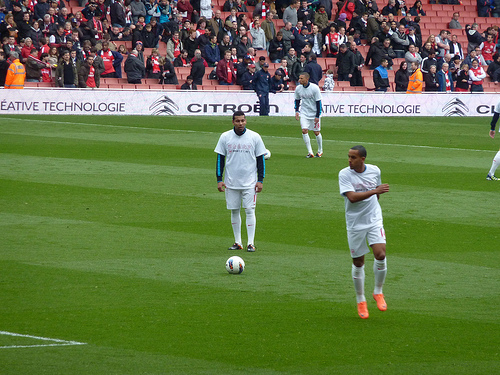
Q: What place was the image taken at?
A: It was taken at the field.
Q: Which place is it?
A: It is a field.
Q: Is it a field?
A: Yes, it is a field.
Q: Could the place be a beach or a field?
A: It is a field.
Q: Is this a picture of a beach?
A: No, the picture is showing a field.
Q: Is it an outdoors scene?
A: Yes, it is outdoors.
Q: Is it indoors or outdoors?
A: It is outdoors.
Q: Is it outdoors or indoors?
A: It is outdoors.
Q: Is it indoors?
A: No, it is outdoors.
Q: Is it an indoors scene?
A: No, it is outdoors.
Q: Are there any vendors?
A: No, there are no vendors.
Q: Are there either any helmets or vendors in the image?
A: No, there are no vendors or helmets.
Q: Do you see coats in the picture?
A: Yes, there is a coat.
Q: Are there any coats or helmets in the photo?
A: Yes, there is a coat.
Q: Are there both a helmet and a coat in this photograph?
A: No, there is a coat but no helmets.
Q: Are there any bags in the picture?
A: No, there are no bags.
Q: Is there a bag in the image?
A: No, there are no bags.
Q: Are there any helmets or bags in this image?
A: No, there are no bags or helmets.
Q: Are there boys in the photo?
A: No, there are no boys.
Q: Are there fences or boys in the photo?
A: No, there are no boys or fences.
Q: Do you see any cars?
A: No, there are no cars.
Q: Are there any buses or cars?
A: No, there are no cars or buses.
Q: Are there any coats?
A: Yes, there is a coat.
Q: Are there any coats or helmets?
A: Yes, there is a coat.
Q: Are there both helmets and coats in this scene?
A: No, there is a coat but no helmets.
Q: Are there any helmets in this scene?
A: No, there are no helmets.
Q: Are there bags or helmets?
A: No, there are no helmets or bags.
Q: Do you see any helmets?
A: No, there are no helmets.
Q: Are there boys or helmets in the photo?
A: No, there are no helmets or boys.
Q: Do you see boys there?
A: No, there are no boys.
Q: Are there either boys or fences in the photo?
A: No, there are no boys or fences.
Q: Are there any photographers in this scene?
A: No, there are no photographers.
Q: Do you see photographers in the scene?
A: No, there are no photographers.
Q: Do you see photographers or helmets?
A: No, there are no photographers or helmets.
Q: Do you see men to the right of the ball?
A: Yes, there is a man to the right of the ball.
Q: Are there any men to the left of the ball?
A: No, the man is to the right of the ball.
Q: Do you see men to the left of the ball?
A: No, the man is to the right of the ball.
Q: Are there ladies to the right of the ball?
A: No, there is a man to the right of the ball.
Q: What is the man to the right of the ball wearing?
A: The man is wearing a shirt.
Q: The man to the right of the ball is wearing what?
A: The man is wearing a shirt.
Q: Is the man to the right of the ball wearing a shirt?
A: Yes, the man is wearing a shirt.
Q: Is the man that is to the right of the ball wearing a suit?
A: No, the man is wearing a shirt.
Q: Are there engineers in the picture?
A: No, there are no engineers.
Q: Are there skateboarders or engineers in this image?
A: No, there are no engineers or skateboarders.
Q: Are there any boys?
A: No, there are no boys.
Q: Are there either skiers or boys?
A: No, there are no boys or skiers.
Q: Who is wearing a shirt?
A: The man is wearing a shirt.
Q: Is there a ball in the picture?
A: Yes, there is a ball.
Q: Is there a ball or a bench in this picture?
A: Yes, there is a ball.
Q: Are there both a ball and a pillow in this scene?
A: No, there is a ball but no pillows.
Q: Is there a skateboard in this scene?
A: No, there are no skateboards.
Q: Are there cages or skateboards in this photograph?
A: No, there are no skateboards or cages.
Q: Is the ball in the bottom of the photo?
A: Yes, the ball is in the bottom of the image.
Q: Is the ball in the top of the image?
A: No, the ball is in the bottom of the image.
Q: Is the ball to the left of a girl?
A: No, the ball is to the left of a man.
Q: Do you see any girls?
A: No, there are no girls.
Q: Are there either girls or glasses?
A: No, there are no girls or glasses.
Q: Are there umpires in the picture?
A: No, there are no umpires.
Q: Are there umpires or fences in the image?
A: No, there are no umpires or fences.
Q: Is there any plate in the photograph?
A: No, there are no plates.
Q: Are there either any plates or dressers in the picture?
A: No, there are no plates or dressers.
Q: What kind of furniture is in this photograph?
A: The furniture is chairs.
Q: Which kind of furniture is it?
A: The pieces of furniture are chairs.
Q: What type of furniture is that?
A: These are chairs.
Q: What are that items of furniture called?
A: These are chairs.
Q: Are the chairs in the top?
A: Yes, the chairs are in the top of the image.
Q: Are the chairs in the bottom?
A: No, the chairs are in the top of the image.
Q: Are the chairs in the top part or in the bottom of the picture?
A: The chairs are in the top of the image.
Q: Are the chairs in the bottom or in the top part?
A: The chairs are in the top of the image.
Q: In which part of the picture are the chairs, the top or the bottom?
A: The chairs are in the top of the image.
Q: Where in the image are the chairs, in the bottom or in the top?
A: The chairs are in the top of the image.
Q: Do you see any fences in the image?
A: No, there are no fences.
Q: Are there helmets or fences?
A: No, there are no fences or helmets.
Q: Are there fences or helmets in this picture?
A: No, there are no fences or helmets.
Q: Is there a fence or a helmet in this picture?
A: No, there are no fences or helmets.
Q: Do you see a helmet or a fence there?
A: No, there are no fences or helmets.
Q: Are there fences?
A: No, there are no fences.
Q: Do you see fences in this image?
A: No, there are no fences.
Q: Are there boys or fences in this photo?
A: No, there are no fences or boys.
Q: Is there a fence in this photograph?
A: No, there are no fences.